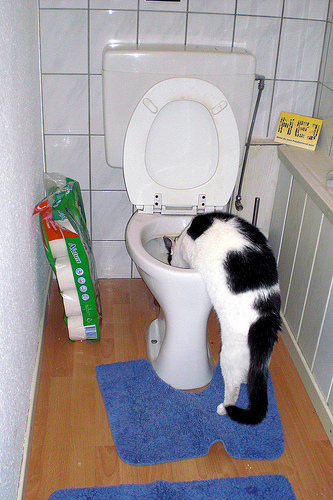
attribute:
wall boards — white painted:
[266, 147, 332, 450]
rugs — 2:
[44, 355, 297, 498]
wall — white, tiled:
[39, 0, 332, 279]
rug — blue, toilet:
[83, 350, 276, 408]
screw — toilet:
[150, 334, 158, 349]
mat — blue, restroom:
[79, 351, 297, 465]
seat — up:
[136, 76, 228, 211]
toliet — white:
[101, 34, 312, 388]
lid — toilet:
[117, 71, 242, 209]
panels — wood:
[270, 159, 331, 405]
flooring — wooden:
[22, 367, 120, 476]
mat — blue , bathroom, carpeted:
[96, 358, 284, 464]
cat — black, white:
[164, 202, 298, 444]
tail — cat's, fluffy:
[216, 342, 271, 429]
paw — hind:
[216, 401, 229, 415]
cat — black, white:
[167, 210, 286, 425]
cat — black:
[170, 220, 289, 345]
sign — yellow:
[274, 111, 322, 151]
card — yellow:
[272, 109, 321, 150]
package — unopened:
[23, 176, 120, 419]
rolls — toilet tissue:
[42, 227, 95, 259]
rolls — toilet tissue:
[44, 263, 98, 281]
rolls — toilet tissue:
[65, 284, 136, 322]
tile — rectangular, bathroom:
[48, 14, 79, 85]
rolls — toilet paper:
[31, 169, 106, 346]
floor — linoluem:
[37, 281, 331, 492]